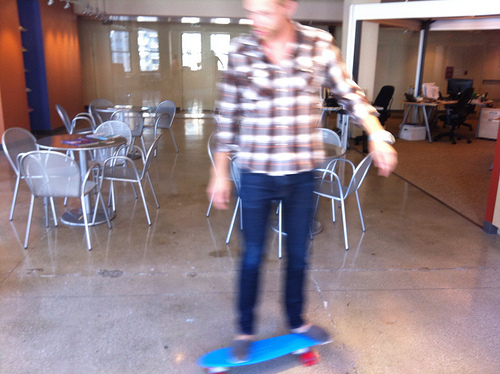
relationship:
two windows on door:
[181, 30, 228, 75] [178, 27, 230, 120]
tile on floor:
[344, 269, 389, 304] [8, 130, 488, 365]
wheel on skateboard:
[296, 349, 321, 367] [189, 323, 335, 370]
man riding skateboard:
[203, 0, 398, 362] [200, 328, 335, 373]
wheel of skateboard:
[296, 347, 326, 367] [192, 320, 362, 371]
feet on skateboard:
[290, 315, 332, 343] [192, 333, 339, 369]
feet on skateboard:
[226, 329, 258, 361] [192, 333, 339, 369]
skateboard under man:
[195, 331, 322, 373] [171, 22, 369, 264]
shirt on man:
[196, 49, 336, 165] [203, 0, 398, 362]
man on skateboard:
[203, 0, 398, 362] [195, 332, 320, 372]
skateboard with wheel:
[178, 287, 369, 360] [296, 349, 321, 367]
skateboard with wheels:
[178, 287, 369, 360] [203, 361, 229, 371]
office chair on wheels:
[428, 82, 479, 146] [430, 130, 475, 146]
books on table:
[62, 130, 121, 152] [34, 132, 128, 230]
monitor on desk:
[445, 75, 475, 97] [403, 92, 490, 105]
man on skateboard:
[203, 0, 398, 362] [189, 323, 335, 370]